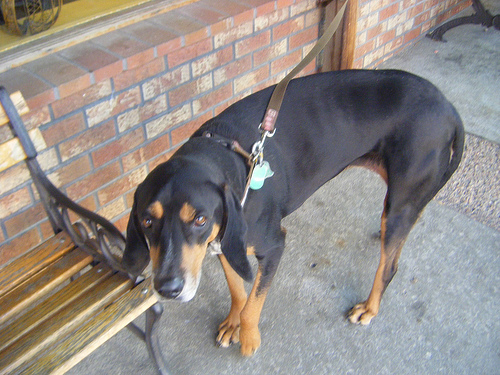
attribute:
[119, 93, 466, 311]
dog — looking, black, brown, scared, fluffy, standing, small, walking, watching, close, sitting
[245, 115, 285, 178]
leash — brown, close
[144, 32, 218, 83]
wall — brick, close, red, brown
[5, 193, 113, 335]
bench — brown, wooden, wood, black, close